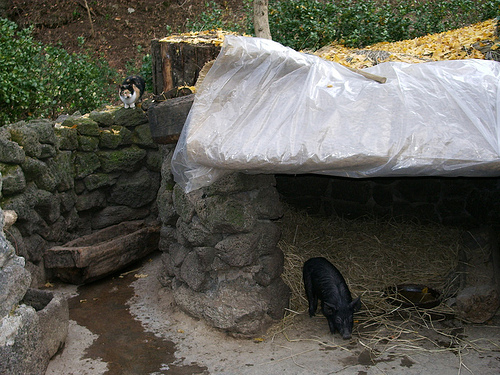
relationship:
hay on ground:
[268, 191, 500, 375] [99, 308, 286, 370]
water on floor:
[78, 295, 183, 374] [272, 343, 408, 372]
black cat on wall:
[118, 75, 147, 109] [0, 98, 165, 373]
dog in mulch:
[118, 75, 145, 110] [79, 18, 499, 115]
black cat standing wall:
[118, 75, 147, 109] [0, 18, 498, 371]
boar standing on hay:
[302, 257, 362, 341] [278, 201, 471, 322]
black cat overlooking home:
[118, 75, 147, 109] [143, 90, 464, 320]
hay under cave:
[283, 201, 488, 351] [150, 43, 499, 350]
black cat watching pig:
[118, 75, 147, 109] [301, 255, 363, 341]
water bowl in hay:
[387, 282, 443, 314] [279, 225, 449, 346]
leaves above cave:
[344, 28, 499, 78] [166, 151, 499, 346]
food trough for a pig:
[66, 195, 135, 347] [247, 264, 392, 375]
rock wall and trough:
[58, 127, 116, 202] [145, 180, 257, 375]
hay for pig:
[268, 191, 500, 375] [301, 255, 363, 341]